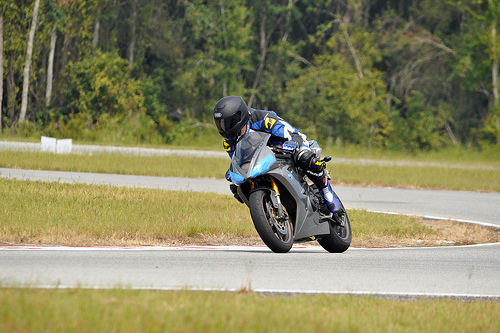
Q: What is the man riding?
A: A bike.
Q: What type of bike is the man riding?
A: Motorcycle.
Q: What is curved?
A: The road.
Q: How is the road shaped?
A: Curvy.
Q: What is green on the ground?
A: Grass.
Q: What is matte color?
A: The helmet.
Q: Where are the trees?
A: Around the track.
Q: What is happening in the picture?
A: A person is riding a motorcycle.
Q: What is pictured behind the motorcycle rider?
A: Trees with green leaves.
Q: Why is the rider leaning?
A: The person is going around a bend.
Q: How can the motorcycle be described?
A: It is blue and grey.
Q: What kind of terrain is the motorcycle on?
A: Asphalt.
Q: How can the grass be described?
A: Dry.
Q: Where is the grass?
A: Next to the road.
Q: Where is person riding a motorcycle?
A: On a paved road.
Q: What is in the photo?
A: A bicycle.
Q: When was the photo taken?
A: Daytime.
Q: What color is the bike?
A: Black.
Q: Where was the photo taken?
A: On the street.